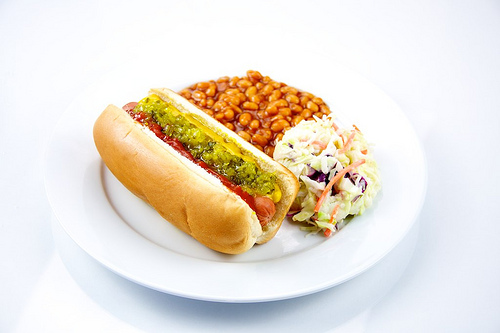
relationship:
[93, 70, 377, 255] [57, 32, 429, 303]
food on plate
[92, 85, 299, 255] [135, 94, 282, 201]
hotdog has condiments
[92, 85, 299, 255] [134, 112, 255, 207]
hotdog has ketchup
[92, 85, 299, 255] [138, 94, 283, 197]
hotdog has condiments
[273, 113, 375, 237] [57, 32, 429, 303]
coleslaw on plate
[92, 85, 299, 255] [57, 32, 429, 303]
hotdog on plate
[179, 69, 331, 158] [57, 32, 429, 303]
beans are on plate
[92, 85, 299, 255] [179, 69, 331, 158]
hotdog with beans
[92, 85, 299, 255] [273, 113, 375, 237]
hotdog with coleslaw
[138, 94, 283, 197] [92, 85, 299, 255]
condiments on hotdog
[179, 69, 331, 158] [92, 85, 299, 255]
beans are next to hotdog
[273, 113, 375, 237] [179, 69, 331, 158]
coleslaw next to beans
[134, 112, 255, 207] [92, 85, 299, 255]
ketchup on hotdog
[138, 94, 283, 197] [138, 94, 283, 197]
condiments next to condiments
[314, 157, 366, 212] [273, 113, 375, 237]
carrot in coleslaw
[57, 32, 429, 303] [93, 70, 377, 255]
plate has food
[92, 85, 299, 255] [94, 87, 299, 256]
hotdog has bun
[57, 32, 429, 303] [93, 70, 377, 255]
plate filled with food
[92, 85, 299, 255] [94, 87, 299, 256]
hotdog in middle of bun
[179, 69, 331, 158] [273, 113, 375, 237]
beans are next to coleslaw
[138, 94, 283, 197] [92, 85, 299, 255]
condiments on top of hotdog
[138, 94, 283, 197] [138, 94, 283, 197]
condiments on side of condiments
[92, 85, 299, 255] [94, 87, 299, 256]
hotdog in bun